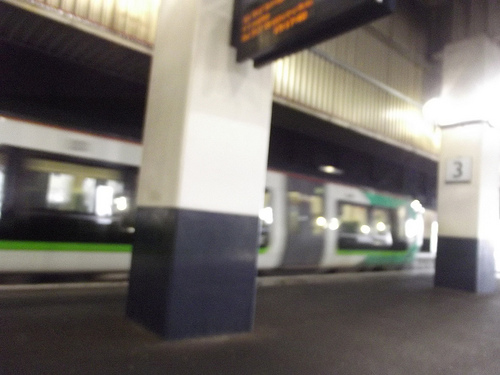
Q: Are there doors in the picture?
A: Yes, there are doors.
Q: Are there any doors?
A: Yes, there are doors.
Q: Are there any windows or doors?
A: Yes, there are doors.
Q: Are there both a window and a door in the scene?
A: Yes, there are both a door and a window.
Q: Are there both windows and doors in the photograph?
A: Yes, there are both doors and windows.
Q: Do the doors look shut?
A: Yes, the doors are shut.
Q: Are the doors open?
A: No, the doors are shut.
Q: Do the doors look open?
A: No, the doors are shut.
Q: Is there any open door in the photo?
A: No, there are doors but they are shut.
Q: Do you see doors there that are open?
A: No, there are doors but they are shut.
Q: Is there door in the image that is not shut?
A: No, there are doors but they are shut.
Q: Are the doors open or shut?
A: The doors are shut.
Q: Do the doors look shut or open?
A: The doors are shut.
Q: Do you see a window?
A: Yes, there are windows.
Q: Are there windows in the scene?
A: Yes, there are windows.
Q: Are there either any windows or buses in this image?
A: Yes, there are windows.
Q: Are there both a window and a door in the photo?
A: Yes, there are both a window and a door.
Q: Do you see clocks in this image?
A: No, there are no clocks.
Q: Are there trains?
A: Yes, there is a train.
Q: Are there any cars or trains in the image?
A: Yes, there is a train.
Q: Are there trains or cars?
A: Yes, there is a train.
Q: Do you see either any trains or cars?
A: Yes, there is a train.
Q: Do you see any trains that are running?
A: Yes, there is a train that is running.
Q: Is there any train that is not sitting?
A: Yes, there is a train that is running.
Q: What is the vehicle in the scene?
A: The vehicle is a train.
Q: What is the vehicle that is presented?
A: The vehicle is a train.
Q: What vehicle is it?
A: The vehicle is a train.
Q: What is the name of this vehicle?
A: This is a train.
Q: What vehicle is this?
A: This is a train.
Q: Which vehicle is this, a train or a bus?
A: This is a train.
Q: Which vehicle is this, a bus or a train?
A: This is a train.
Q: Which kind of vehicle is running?
A: The vehicle is a train.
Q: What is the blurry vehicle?
A: The vehicle is a train.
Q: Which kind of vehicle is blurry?
A: The vehicle is a train.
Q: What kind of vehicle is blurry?
A: The vehicle is a train.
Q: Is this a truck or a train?
A: This is a train.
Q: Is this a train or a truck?
A: This is a train.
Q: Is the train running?
A: Yes, the train is running.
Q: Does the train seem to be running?
A: Yes, the train is running.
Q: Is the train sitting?
A: No, the train is running.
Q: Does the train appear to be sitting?
A: No, the train is running.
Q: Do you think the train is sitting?
A: No, the train is running.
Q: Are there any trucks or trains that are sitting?
A: No, there is a train but it is running.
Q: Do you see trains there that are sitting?
A: No, there is a train but it is running.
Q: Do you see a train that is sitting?
A: No, there is a train but it is running.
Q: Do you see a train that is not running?
A: No, there is a train but it is running.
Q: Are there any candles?
A: No, there are no candles.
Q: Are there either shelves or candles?
A: No, there are no candles or shelves.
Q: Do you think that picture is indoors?
A: Yes, the picture is indoors.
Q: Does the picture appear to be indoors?
A: Yes, the picture is indoors.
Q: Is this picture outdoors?
A: No, the picture is indoors.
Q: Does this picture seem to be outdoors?
A: No, the picture is indoors.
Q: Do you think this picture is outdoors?
A: No, the picture is indoors.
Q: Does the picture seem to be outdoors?
A: No, the picture is indoors.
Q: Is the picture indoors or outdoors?
A: The picture is indoors.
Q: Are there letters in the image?
A: Yes, there are letters.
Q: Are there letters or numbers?
A: Yes, there are letters.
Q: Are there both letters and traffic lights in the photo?
A: No, there are letters but no traffic lights.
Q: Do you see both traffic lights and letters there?
A: No, there are letters but no traffic lights.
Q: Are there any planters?
A: No, there are no planters.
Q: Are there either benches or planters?
A: No, there are no planters or benches.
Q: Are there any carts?
A: No, there are no carts.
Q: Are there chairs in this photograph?
A: No, there are no chairs.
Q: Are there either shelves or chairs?
A: No, there are no chairs or shelves.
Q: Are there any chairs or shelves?
A: No, there are no chairs or shelves.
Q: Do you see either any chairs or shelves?
A: No, there are no chairs or shelves.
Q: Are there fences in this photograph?
A: No, there are no fences.